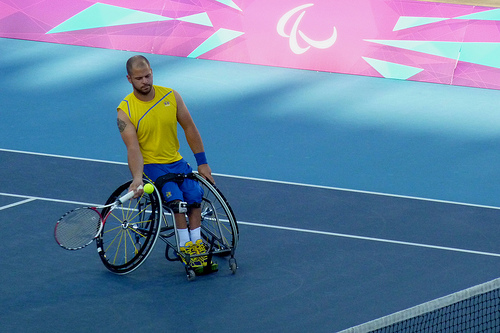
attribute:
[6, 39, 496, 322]
tennis court — blue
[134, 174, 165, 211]
ball — green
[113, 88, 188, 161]
shirt — yellow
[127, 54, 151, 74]
hair — short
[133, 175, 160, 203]
tennis ball — yellow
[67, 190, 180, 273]
wheel — large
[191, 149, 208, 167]
wristband — blue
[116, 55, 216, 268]
man — wearing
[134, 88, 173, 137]
stripe — blue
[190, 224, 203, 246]
sock — white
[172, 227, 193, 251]
sock — white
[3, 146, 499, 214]
line — white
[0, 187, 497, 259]
line — white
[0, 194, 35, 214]
line — white